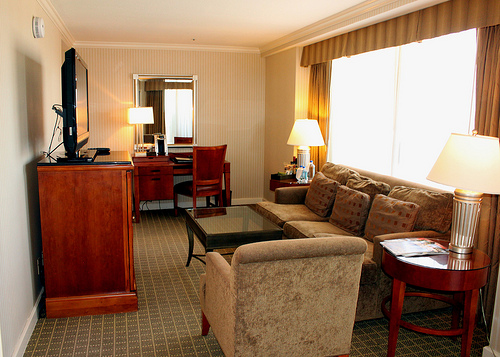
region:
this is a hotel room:
[37, 23, 487, 353]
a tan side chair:
[188, 220, 392, 352]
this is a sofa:
[258, 123, 468, 320]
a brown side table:
[366, 218, 497, 355]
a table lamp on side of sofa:
[416, 105, 498, 272]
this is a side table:
[373, 220, 475, 352]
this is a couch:
[262, 151, 474, 333]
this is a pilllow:
[305, 163, 337, 220]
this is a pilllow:
[325, 180, 371, 245]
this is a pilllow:
[377, 165, 457, 240]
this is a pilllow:
[360, 185, 445, 244]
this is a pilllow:
[345, 168, 390, 210]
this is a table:
[185, 194, 268, 268]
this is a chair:
[177, 140, 237, 210]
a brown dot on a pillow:
[397, 220, 409, 230]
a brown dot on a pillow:
[390, 220, 399, 231]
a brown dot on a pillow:
[377, 216, 382, 225]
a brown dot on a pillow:
[408, 200, 417, 212]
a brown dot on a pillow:
[355, 201, 364, 211]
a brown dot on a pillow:
[346, 215, 356, 225]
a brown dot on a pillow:
[318, 198, 325, 205]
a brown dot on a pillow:
[347, 197, 362, 217]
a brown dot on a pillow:
[314, 193, 326, 208]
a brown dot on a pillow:
[353, 220, 363, 230]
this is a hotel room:
[22, 13, 497, 342]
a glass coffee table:
[163, 174, 290, 294]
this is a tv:
[26, 20, 116, 182]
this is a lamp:
[395, 93, 499, 270]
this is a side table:
[346, 220, 493, 353]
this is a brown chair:
[174, 209, 379, 354]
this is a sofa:
[220, 105, 462, 317]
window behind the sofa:
[303, 29, 476, 189]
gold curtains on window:
[266, 0, 498, 235]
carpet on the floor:
[53, 297, 207, 353]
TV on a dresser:
[61, 38, 96, 160]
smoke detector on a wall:
[31, 18, 51, 40]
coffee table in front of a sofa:
[184, 189, 290, 253]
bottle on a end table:
[290, 160, 312, 182]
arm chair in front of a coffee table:
[188, 228, 363, 353]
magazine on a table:
[385, 229, 442, 266]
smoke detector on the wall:
[28, 14, 51, 41]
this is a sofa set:
[258, 153, 468, 316]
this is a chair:
[173, 125, 234, 200]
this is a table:
[370, 230, 497, 345]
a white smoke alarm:
[25, 7, 49, 42]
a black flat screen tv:
[45, 43, 117, 170]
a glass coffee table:
[176, 199, 306, 296]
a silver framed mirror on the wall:
[119, 63, 206, 158]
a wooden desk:
[127, 138, 244, 220]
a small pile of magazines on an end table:
[367, 233, 486, 350]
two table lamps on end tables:
[270, 104, 498, 271]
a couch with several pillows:
[249, 143, 459, 325]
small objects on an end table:
[272, 150, 326, 190]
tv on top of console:
[30, 17, 155, 335]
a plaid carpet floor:
[35, 179, 461, 355]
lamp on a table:
[408, 125, 498, 255]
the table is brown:
[372, 233, 497, 349]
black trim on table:
[178, 209, 280, 263]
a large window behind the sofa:
[276, 7, 498, 197]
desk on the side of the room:
[106, 141, 234, 211]